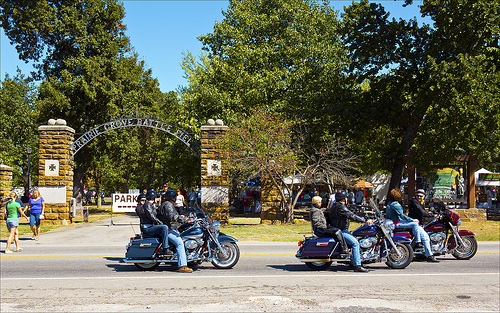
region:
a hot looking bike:
[113, 155, 271, 304]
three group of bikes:
[104, 170, 466, 311]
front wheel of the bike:
[211, 245, 253, 270]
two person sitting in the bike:
[132, 175, 199, 282]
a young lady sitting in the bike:
[385, 185, 428, 257]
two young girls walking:
[1, 177, 58, 259]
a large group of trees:
[62, 13, 499, 150]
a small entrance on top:
[53, 117, 257, 180]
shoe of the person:
[171, 262, 202, 279]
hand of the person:
[343, 207, 378, 231]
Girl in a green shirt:
[5, 186, 22, 252]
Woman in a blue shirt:
[29, 186, 48, 238]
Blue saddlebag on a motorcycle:
[118, 227, 165, 269]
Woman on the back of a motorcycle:
[139, 190, 168, 241]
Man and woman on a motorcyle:
[305, 183, 365, 273]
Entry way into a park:
[37, 109, 241, 203]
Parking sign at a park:
[108, 188, 140, 215]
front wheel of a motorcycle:
[208, 230, 242, 267]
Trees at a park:
[262, 46, 484, 163]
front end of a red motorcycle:
[430, 195, 487, 260]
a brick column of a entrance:
[38, 120, 71, 215]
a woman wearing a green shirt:
[2, 191, 25, 219]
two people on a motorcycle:
[126, 180, 227, 265]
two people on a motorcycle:
[296, 185, 378, 265]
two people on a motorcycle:
[390, 180, 465, 245]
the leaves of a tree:
[271, 50, 311, 95]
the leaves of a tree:
[70, 61, 111, 91]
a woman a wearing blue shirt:
[25, 187, 50, 212]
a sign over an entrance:
[75, 113, 199, 158]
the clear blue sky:
[155, 22, 177, 48]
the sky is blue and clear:
[109, 6, 273, 93]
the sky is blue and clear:
[93, 1, 288, 221]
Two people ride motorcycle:
[117, 189, 242, 256]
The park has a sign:
[39, 82, 248, 167]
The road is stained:
[275, 263, 326, 307]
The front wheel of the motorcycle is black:
[200, 217, 254, 277]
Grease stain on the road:
[440, 286, 485, 310]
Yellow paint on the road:
[19, 244, 109, 269]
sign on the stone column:
[37, 155, 76, 185]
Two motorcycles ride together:
[282, 177, 497, 296]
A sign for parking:
[99, 178, 153, 248]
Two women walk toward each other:
[9, 187, 74, 254]